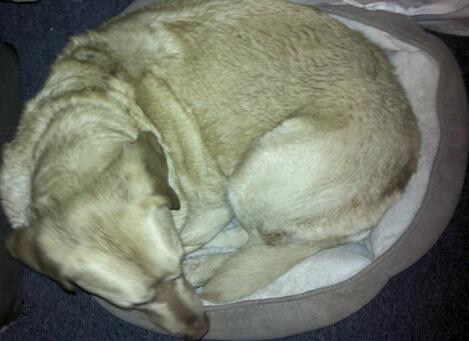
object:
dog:
[0, 1, 423, 340]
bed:
[78, 0, 469, 327]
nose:
[180, 319, 216, 340]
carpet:
[1, 1, 131, 133]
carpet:
[0, 254, 467, 337]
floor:
[2, 1, 469, 338]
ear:
[131, 129, 186, 214]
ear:
[5, 226, 73, 298]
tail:
[200, 189, 404, 306]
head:
[7, 140, 209, 338]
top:
[31, 156, 125, 239]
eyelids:
[130, 290, 158, 309]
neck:
[18, 110, 135, 201]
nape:
[24, 91, 119, 133]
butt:
[337, 100, 427, 254]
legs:
[199, 107, 397, 305]